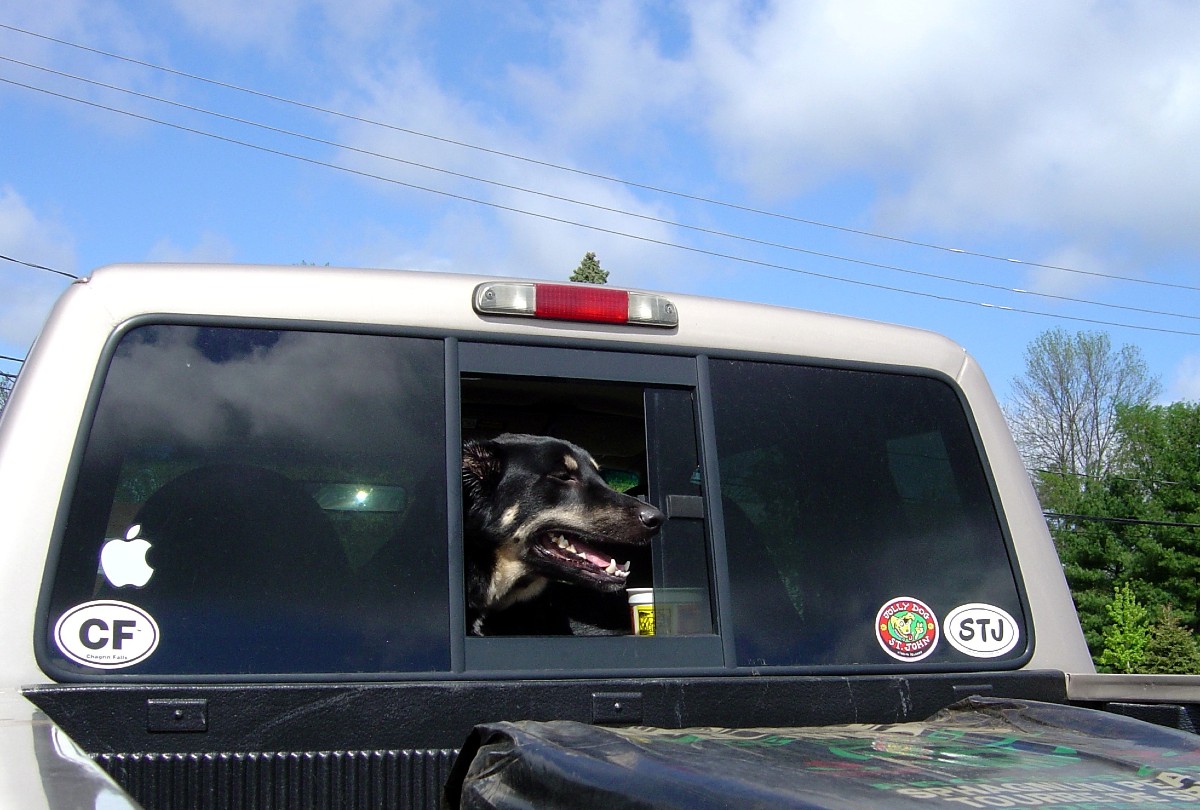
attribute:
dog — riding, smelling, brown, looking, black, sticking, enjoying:
[456, 434, 686, 608]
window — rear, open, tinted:
[224, 280, 822, 568]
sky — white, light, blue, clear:
[322, 46, 835, 218]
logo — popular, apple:
[70, 501, 282, 648]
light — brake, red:
[471, 215, 806, 371]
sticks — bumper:
[784, 570, 1105, 682]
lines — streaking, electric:
[126, 30, 467, 146]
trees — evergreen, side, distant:
[1058, 410, 1194, 620]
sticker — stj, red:
[949, 575, 1054, 678]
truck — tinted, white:
[257, 253, 1105, 612]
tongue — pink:
[563, 526, 668, 611]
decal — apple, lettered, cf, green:
[47, 508, 212, 655]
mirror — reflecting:
[340, 448, 423, 513]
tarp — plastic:
[567, 693, 933, 809]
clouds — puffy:
[650, 35, 1065, 205]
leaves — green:
[1047, 396, 1152, 521]